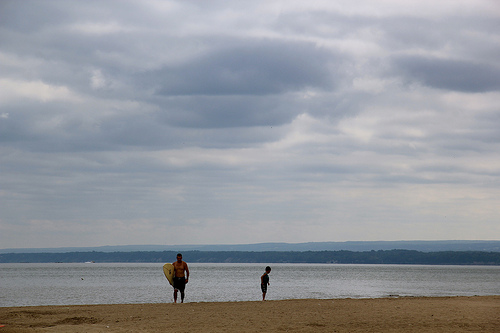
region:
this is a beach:
[29, 236, 493, 330]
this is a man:
[148, 244, 200, 304]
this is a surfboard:
[154, 250, 179, 287]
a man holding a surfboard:
[154, 241, 200, 313]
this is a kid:
[257, 244, 289, 321]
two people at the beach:
[140, 236, 339, 326]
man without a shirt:
[160, 247, 191, 281]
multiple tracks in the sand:
[9, 299, 448, 331]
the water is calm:
[0, 251, 495, 316]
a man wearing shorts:
[168, 274, 192, 295]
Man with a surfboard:
[158, 250, 193, 307]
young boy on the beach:
[255, 263, 282, 307]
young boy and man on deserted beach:
[146, 248, 306, 313]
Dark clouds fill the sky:
[6, 0, 498, 248]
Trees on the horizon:
[5, 245, 498, 265]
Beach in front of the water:
[5, 292, 499, 329]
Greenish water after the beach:
[3, 259, 496, 301]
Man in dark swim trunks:
[145, 249, 197, 308]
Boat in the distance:
[75, 256, 98, 267]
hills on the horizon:
[8, 238, 497, 253]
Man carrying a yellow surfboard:
[160, 250, 193, 304]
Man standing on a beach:
[160, 248, 191, 303]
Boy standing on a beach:
[257, 264, 275, 303]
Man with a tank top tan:
[160, 252, 194, 307]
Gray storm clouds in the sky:
[0, 0, 499, 244]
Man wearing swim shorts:
[161, 250, 193, 304]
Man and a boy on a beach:
[160, 250, 275, 302]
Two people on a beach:
[160, 247, 272, 304]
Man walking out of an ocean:
[160, 249, 195, 304]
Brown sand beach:
[1, 290, 498, 332]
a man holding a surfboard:
[160, 251, 191, 303]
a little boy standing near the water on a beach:
[257, 265, 273, 300]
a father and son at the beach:
[160, 250, 270, 303]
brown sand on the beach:
[270, 300, 495, 330]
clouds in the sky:
[0, 0, 496, 186]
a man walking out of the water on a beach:
[160, 250, 190, 300]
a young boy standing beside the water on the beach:
[256, 261, 271, 296]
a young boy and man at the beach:
[160, 250, 270, 301]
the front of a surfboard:
[160, 262, 175, 284]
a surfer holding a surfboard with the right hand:
[160, 250, 191, 302]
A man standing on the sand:
[161, 254, 188, 302]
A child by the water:
[260, 266, 272, 299]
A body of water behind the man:
[1, 265, 498, 305]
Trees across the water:
[0, 250, 498, 264]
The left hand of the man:
[186, 276, 191, 282]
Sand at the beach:
[1, 294, 498, 331]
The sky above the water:
[0, 0, 497, 249]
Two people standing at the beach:
[163, 253, 271, 300]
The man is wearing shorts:
[171, 276, 184, 291]